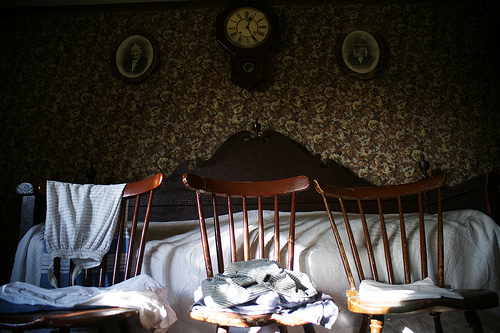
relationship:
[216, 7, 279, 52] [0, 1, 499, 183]
clock hanging on wall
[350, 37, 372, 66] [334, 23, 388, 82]
man in picture frame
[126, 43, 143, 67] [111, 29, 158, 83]
lady in picture frame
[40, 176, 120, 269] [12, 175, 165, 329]
pajamas on chair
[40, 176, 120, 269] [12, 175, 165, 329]
pajamas hanging on chair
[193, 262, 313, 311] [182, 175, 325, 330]
chothes on chair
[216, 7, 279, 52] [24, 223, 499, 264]
clock above bed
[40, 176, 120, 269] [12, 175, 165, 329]
pajamas over a chair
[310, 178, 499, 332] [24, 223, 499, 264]
wooden chair near bed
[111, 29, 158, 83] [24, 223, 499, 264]
oval picture above bed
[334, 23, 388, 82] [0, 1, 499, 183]
picture frame on wall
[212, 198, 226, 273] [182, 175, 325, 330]
wooden rod on chair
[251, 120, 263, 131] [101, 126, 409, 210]
wooden ball on head board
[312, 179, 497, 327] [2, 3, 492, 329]
wooden chair in room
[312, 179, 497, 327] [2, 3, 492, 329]
chair in room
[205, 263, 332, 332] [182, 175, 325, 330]
pile of clothing on top of chair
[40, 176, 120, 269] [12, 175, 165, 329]
pair of pants hanging on chair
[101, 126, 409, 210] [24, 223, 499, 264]
head board on bed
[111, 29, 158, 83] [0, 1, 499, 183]
portrait on wall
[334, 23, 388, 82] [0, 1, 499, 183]
portrait on wall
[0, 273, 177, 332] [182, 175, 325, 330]
clothing laying on chair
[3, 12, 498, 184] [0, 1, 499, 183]
print wallpaper on wall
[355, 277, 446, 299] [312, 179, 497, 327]
towel on chair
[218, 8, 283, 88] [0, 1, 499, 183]
old clock on wall